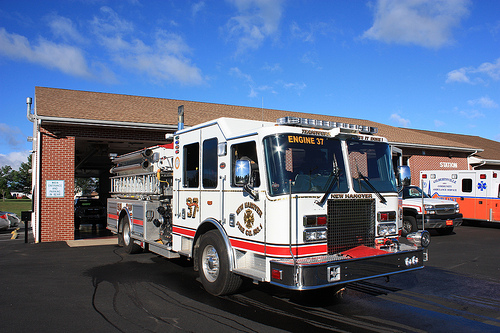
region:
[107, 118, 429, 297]
firetruck in driveway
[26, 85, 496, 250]
firehouse with parked fire trucks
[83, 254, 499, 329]
water running on street from firetruck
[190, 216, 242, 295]
front right wheel on firetruck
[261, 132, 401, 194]
front windows on firetruck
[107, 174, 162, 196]
ladder on side of firetruck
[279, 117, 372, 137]
light on top of fire truck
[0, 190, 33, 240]
grassy area on side of building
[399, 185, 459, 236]
white truck parked next to firetruck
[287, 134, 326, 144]
engine 37 text on firetruck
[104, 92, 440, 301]
orange and white fire truck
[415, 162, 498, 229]
Orange and white ambulance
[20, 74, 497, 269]
Brick fire station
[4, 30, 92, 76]
Fluffy white clouds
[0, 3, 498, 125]
Fluffy white clouds in sky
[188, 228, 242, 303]
Black wheel on fire truck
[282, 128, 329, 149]
ENGINE 37 on fire truck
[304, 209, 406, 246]
Lights on front of fire truck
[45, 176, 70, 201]
White sign on building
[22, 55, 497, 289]
Building and emergency vehicles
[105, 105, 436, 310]
Fire engine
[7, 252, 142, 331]
Paved front of the yard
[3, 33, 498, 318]
Fire station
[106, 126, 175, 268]
Firefighting equipment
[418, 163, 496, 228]
Fire ambulance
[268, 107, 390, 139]
Strobe lights and sirens of the fire engine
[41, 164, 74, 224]
Poster on the wall of the entrance of a building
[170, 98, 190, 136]
Exhaust pipe of the fire engine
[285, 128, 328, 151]
Number of the fire engine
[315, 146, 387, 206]
Windshield wipers of the fire engine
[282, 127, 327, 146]
Engine 37 written in yellow letters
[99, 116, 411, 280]
truck with white front and silver back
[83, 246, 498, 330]
water streaks on ground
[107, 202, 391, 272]
red stripe along bottom of truck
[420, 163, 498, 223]
orange and white ambulance truck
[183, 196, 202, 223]
Number 37 printed on side of truck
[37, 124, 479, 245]
red brick fire station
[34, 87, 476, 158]
brown roof on red building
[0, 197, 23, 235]
cars parked on side of building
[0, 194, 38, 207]
partial view of grass behind fire station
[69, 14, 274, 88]
the sky is blue and clear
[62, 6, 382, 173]
the sky is blue and clear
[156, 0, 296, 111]
the sky is blue and clear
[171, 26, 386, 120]
the sky is blue and clear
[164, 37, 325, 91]
the sky is blue and clear